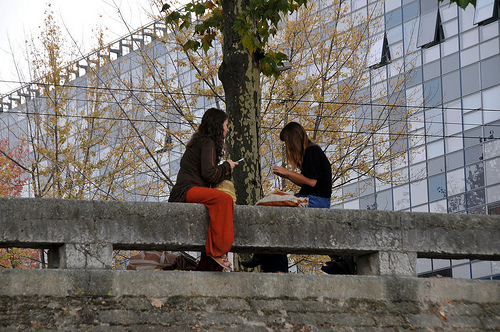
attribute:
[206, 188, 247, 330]
pants — loose, orange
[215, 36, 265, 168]
trunk — large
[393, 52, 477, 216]
windows — tinted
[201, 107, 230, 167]
hair — curly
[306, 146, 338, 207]
shirt — black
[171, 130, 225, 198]
shirt — brown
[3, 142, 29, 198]
leaves — orange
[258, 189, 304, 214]
bag — big, two-toned, brown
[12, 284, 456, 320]
stone — grey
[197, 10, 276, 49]
leaves — turning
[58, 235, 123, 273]
pillar — grey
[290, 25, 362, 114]
leaves — gold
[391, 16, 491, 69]
windows — grey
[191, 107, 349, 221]
women — sitting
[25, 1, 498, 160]
building — big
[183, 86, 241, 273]
woman — texting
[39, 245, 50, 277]
trunk — skinny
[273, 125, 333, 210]
woman — texting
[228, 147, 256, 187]
phone — mobile, grey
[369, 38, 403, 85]
window — open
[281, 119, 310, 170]
hair — long